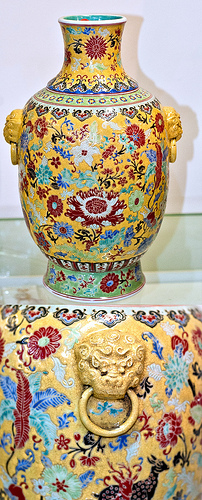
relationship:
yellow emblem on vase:
[168, 107, 181, 165] [3, 15, 181, 300]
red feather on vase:
[7, 368, 30, 475] [3, 15, 181, 300]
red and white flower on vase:
[66, 187, 126, 226] [3, 15, 181, 300]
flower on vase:
[34, 462, 84, 499] [3, 15, 181, 300]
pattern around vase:
[30, 87, 155, 106] [3, 15, 181, 300]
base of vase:
[45, 263, 146, 302] [3, 15, 181, 300]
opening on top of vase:
[59, 14, 124, 24] [3, 15, 181, 300]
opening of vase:
[59, 14, 124, 24] [3, 15, 181, 300]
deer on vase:
[92, 455, 168, 500] [3, 15, 181, 300]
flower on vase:
[28, 326, 62, 359] [3, 15, 181, 300]